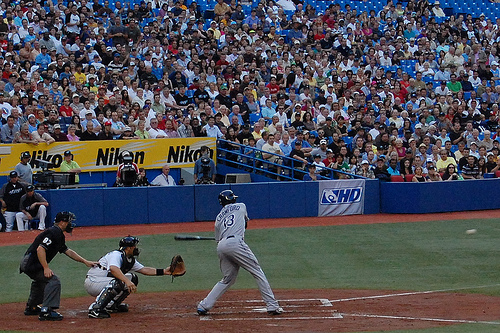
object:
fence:
[35, 178, 500, 229]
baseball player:
[196, 189, 283, 315]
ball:
[465, 228, 477, 235]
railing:
[216, 139, 367, 182]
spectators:
[2, 2, 499, 181]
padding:
[43, 177, 497, 217]